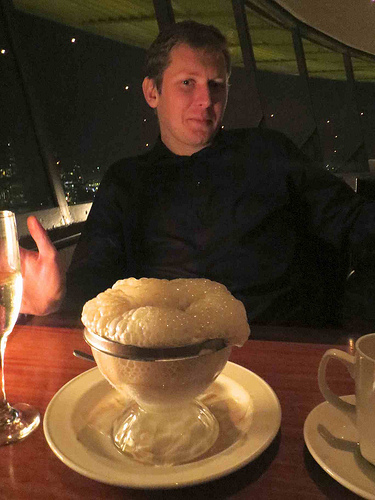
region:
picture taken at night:
[0, 8, 374, 235]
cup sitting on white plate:
[41, 274, 272, 484]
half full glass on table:
[1, 204, 42, 454]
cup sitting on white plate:
[302, 318, 373, 496]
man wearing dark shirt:
[41, 18, 360, 339]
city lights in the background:
[0, 116, 131, 242]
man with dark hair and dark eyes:
[134, 10, 234, 166]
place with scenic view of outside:
[0, 0, 363, 266]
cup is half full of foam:
[35, 277, 277, 487]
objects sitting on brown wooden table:
[3, 322, 368, 496]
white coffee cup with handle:
[312, 324, 373, 467]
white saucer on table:
[29, 344, 289, 493]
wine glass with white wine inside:
[1, 204, 42, 458]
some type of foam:
[76, 267, 249, 359]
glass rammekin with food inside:
[81, 316, 248, 467]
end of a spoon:
[63, 342, 99, 368]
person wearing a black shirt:
[0, 24, 374, 350]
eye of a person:
[178, 74, 201, 91]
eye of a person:
[205, 71, 226, 94]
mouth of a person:
[182, 112, 220, 129]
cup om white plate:
[37, 277, 283, 483]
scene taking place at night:
[2, 5, 370, 227]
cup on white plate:
[308, 325, 374, 495]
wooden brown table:
[3, 316, 351, 496]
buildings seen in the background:
[3, 126, 120, 220]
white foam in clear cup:
[52, 270, 259, 471]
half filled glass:
[1, 200, 48, 452]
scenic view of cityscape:
[0, 0, 372, 203]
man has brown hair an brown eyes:
[126, 14, 242, 174]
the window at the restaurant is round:
[67, 21, 353, 468]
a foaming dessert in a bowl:
[43, 244, 279, 471]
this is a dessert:
[36, 222, 264, 488]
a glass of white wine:
[0, 162, 27, 492]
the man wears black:
[95, 16, 318, 228]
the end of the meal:
[49, 23, 329, 481]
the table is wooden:
[40, 5, 334, 459]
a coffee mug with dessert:
[290, 308, 371, 394]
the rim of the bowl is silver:
[60, 6, 318, 465]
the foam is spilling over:
[48, 238, 276, 465]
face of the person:
[151, 18, 265, 137]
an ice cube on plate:
[65, 255, 271, 379]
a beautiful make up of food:
[70, 275, 272, 474]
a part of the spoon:
[62, 328, 103, 375]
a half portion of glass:
[2, 279, 48, 455]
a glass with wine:
[0, 267, 53, 446]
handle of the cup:
[292, 321, 360, 432]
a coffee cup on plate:
[309, 313, 372, 467]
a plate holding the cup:
[292, 407, 356, 499]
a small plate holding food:
[23, 354, 258, 499]